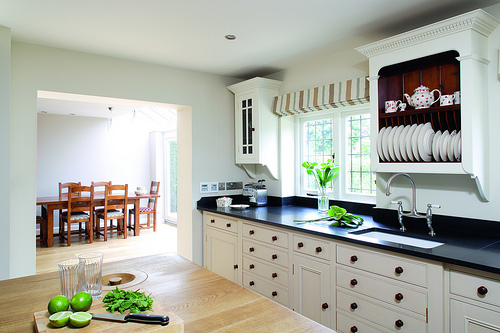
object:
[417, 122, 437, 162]
plate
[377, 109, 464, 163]
rack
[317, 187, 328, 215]
vase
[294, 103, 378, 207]
window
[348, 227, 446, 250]
sink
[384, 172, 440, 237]
faucet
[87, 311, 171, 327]
knife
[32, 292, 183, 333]
board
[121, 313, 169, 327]
handle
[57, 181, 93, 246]
chair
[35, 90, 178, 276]
dining room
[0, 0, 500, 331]
kitchen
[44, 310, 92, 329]
lime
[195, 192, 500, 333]
counter top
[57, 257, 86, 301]
glass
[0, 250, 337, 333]
counter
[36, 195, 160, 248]
table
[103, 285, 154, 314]
herbs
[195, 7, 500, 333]
cabinet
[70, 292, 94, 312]
lime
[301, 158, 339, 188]
flower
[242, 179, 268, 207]
toaster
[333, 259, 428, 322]
drawer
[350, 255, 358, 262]
knob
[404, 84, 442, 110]
teapot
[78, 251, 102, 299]
cup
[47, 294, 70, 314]
lime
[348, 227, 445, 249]
basin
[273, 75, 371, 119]
valance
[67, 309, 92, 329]
lime half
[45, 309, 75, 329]
lime half